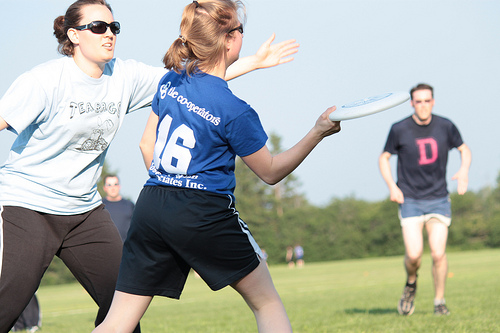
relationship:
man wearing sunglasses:
[338, 78, 482, 307] [410, 98, 432, 104]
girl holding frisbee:
[88, 0, 342, 333] [326, 88, 409, 120]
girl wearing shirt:
[88, 0, 342, 333] [118, 51, 255, 205]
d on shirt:
[416, 138, 437, 166] [382, 111, 464, 196]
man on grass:
[378, 84, 472, 315] [65, 255, 497, 330]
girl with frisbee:
[88, 0, 342, 333] [333, 90, 414, 125]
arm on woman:
[119, 28, 310, 93] [2, 5, 147, 331]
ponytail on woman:
[53, 15, 73, 56] [2, 0, 299, 332]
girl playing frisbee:
[88, 0, 342, 333] [314, 84, 407, 123]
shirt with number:
[142, 65, 267, 195] [153, 114, 196, 175]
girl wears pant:
[88, 0, 342, 333] [0, 184, 167, 331]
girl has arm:
[88, 0, 342, 333] [215, 103, 342, 184]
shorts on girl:
[111, 182, 270, 298] [94, 0, 339, 331]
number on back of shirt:
[146, 111, 202, 176] [141, 73, 269, 190]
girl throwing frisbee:
[94, 0, 339, 331] [326, 90, 411, 119]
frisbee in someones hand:
[324, 86, 414, 124] [302, 105, 365, 163]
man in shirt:
[378, 84, 472, 315] [382, 111, 464, 196]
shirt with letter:
[382, 111, 464, 196] [416, 138, 438, 165]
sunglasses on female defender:
[76, 21, 130, 33] [4, 8, 294, 331]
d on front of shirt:
[415, 136, 438, 167] [387, 112, 462, 199]